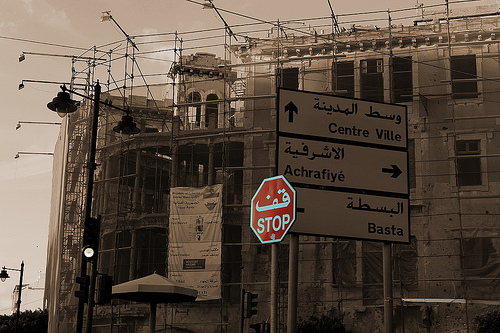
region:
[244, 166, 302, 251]
stop sign in two different languages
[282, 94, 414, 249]
road sign in two different languages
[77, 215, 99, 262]
traffic light on a pole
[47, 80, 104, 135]
street light on a pole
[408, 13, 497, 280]
scaffolding surrounding the building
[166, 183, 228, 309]
banner hanging on the scaffolding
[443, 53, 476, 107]
window in the building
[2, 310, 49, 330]
trees behind the building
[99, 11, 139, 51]
lights coming off the scaffolding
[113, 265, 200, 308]
umbrella open on a pole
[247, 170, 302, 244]
a red plate sign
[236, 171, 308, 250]
a stop sign on a pole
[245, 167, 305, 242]
a traffic sign on a pole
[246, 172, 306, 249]
red plate with stop sign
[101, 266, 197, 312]
tent of a table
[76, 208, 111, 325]
traffic lights on street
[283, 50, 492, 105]
windows of a building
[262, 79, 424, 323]
large street directional signs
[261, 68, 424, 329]
a large plate of traffic signs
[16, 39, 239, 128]
top of a building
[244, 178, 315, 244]
red and white sign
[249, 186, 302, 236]
Arabic characters on sign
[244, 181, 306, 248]
white characters on sign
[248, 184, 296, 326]
sign on grey pole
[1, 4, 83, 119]
thick and cloudy sky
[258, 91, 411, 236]
white and black sign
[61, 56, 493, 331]
scaffolding around building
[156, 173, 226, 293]
white banner hanging on building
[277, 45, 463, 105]
rectangular windows on building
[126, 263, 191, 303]
umbrella is below building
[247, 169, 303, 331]
A red stop sign below a building.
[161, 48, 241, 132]
a tower on top of a building.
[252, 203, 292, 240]
the word stop on a stop sign.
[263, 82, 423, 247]
a sign next to a red stop sign.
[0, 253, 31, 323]
a street light on a street.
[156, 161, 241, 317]
a sign in front of a building.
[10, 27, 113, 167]
a row of lights on a building.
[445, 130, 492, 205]
a window on a building.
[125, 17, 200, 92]
a cloud in a sky.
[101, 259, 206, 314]
an umbrella in front of a building.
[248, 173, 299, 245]
Red traffic stop sign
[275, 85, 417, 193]
Part of directional sign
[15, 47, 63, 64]
Overhead light for building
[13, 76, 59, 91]
Overhead light for building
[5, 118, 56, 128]
Overhead light for building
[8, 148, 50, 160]
Overhead light for building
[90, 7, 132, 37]
Overhead light for building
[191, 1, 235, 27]
Overhead light for building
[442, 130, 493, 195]
Window on tall building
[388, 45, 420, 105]
Window on tall bu ilding